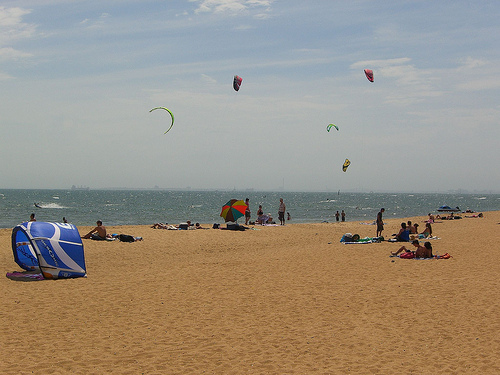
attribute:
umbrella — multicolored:
[225, 200, 247, 219]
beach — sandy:
[53, 133, 460, 340]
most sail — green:
[142, 102, 182, 134]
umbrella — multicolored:
[216, 197, 251, 232]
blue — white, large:
[65, 243, 87, 256]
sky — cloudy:
[1, 0, 498, 191]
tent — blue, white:
[9, 215, 89, 282]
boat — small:
[428, 200, 460, 217]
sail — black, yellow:
[339, 156, 351, 174]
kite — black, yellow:
[338, 156, 352, 176]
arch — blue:
[11, 221, 87, 280]